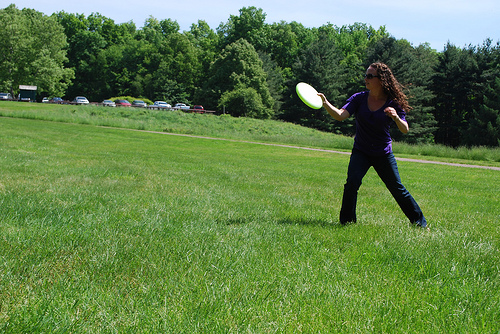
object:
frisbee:
[295, 81, 324, 110]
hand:
[317, 92, 325, 104]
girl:
[317, 61, 430, 230]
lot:
[0, 95, 203, 112]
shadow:
[212, 213, 340, 231]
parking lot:
[0, 84, 206, 112]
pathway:
[97, 124, 499, 171]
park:
[0, 7, 500, 334]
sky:
[0, 1, 500, 56]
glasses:
[362, 74, 379, 79]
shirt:
[340, 90, 407, 156]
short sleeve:
[342, 97, 358, 119]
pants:
[338, 153, 425, 222]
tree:
[0, 4, 79, 99]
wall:
[19, 90, 37, 102]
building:
[16, 84, 37, 103]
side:
[32, 85, 37, 99]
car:
[74, 96, 89, 104]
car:
[71, 96, 91, 104]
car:
[155, 100, 172, 107]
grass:
[0, 100, 500, 334]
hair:
[370, 62, 413, 113]